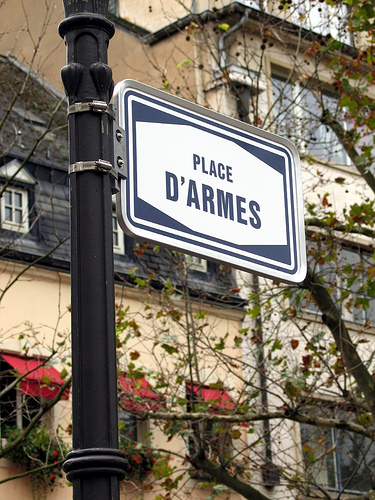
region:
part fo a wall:
[136, 43, 168, 76]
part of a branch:
[207, 461, 227, 486]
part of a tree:
[163, 432, 188, 466]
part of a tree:
[163, 372, 180, 412]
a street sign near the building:
[51, 69, 330, 296]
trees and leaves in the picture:
[140, 299, 354, 473]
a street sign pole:
[49, 18, 115, 260]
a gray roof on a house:
[8, 83, 70, 261]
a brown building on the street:
[126, 13, 374, 104]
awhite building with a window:
[248, 299, 362, 497]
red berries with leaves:
[27, 425, 162, 497]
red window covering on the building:
[4, 345, 66, 410]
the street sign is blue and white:
[111, 76, 320, 278]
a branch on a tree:
[128, 382, 360, 451]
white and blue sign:
[114, 76, 305, 279]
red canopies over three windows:
[7, 349, 240, 420]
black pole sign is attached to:
[61, 2, 134, 494]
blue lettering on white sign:
[159, 142, 272, 228]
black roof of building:
[1, 52, 232, 295]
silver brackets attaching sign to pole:
[64, 99, 129, 184]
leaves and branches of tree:
[91, 1, 365, 498]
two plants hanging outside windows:
[2, 423, 158, 488]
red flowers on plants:
[46, 439, 160, 489]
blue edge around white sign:
[122, 88, 298, 275]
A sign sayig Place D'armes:
[113, 74, 315, 284]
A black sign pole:
[59, 158, 161, 498]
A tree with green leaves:
[255, 332, 351, 463]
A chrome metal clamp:
[54, 84, 114, 182]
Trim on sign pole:
[56, 444, 129, 478]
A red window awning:
[12, 344, 67, 406]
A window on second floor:
[2, 154, 37, 240]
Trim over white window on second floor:
[1, 156, 36, 188]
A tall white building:
[253, 4, 367, 491]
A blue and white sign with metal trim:
[112, 74, 313, 284]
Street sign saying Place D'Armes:
[116, 79, 303, 285]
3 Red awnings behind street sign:
[2, 347, 251, 421]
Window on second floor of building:
[0, 183, 26, 231]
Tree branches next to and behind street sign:
[173, 2, 369, 494]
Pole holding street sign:
[58, 2, 124, 491]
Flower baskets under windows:
[2, 427, 158, 492]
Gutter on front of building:
[236, 86, 276, 480]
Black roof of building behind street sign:
[2, 58, 247, 303]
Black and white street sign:
[118, 79, 309, 281]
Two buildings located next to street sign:
[5, 2, 367, 494]